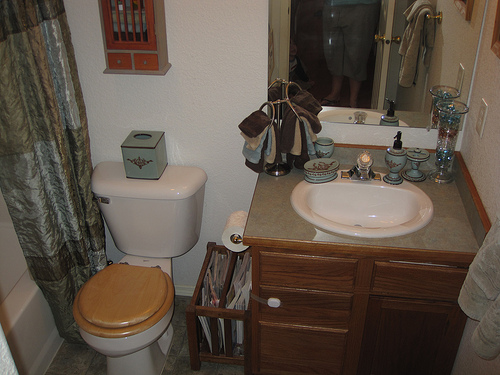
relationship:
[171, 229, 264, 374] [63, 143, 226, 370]
magazine rack next to toilet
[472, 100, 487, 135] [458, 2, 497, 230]
electrical plug on wall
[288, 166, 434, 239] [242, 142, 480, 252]
sink on top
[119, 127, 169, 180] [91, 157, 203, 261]
tissue on tank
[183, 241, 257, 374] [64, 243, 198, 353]
magazine rack by toilet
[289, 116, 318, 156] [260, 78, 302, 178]
sock hanged in holder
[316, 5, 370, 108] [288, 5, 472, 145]
reflection in mirror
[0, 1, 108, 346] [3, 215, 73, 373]
curtain in front of bathtub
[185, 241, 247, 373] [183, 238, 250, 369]
magazines in a rack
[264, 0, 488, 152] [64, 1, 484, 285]
mirror on wall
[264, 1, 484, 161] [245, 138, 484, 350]
mirror over sink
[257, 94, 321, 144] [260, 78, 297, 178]
towel on holder